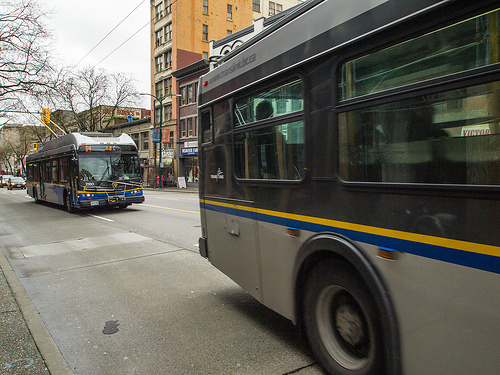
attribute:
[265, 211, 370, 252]
reflector — orange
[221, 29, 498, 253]
bus — grey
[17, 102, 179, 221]
bus — grey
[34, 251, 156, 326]
road — dark grey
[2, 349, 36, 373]
number — blue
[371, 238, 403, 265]
reflector — orange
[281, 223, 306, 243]
reflector — orange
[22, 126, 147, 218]
bus — grey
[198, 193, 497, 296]
stripe — blue, yellow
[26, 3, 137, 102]
sky — grey, cloudy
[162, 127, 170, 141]
sign — blue and orange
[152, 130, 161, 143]
sign — blue and orange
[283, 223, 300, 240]
reflector — orange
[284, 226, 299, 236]
reflector — orange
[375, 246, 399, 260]
reflector — orange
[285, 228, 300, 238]
reflector — orange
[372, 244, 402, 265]
refñector — orange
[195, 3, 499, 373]
bus — grey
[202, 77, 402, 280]
bus — grey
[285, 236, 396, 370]
tire — black